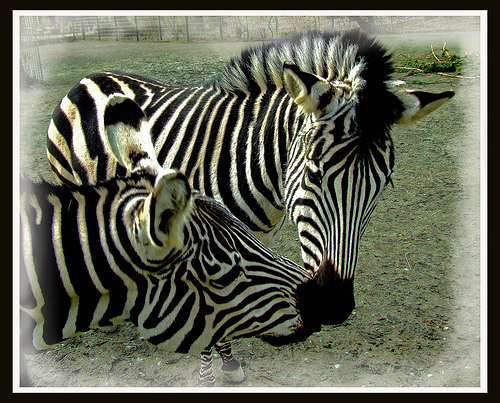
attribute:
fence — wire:
[32, 16, 294, 41]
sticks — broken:
[399, 57, 472, 90]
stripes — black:
[326, 194, 348, 232]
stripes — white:
[170, 117, 276, 161]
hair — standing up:
[214, 28, 397, 93]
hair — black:
[341, 51, 403, 154]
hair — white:
[251, 49, 379, 75]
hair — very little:
[65, 167, 157, 191]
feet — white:
[197, 356, 275, 379]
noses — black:
[272, 255, 370, 343]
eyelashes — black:
[362, 137, 411, 197]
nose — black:
[287, 256, 361, 356]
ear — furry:
[132, 164, 231, 261]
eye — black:
[189, 258, 261, 296]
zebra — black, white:
[57, 33, 427, 328]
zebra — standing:
[58, 42, 398, 358]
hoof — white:
[188, 350, 300, 384]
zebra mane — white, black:
[223, 27, 418, 88]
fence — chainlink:
[23, 31, 312, 73]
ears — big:
[249, 69, 456, 161]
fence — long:
[4, 14, 249, 52]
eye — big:
[193, 246, 282, 292]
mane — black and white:
[173, 14, 393, 154]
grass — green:
[353, 230, 470, 377]